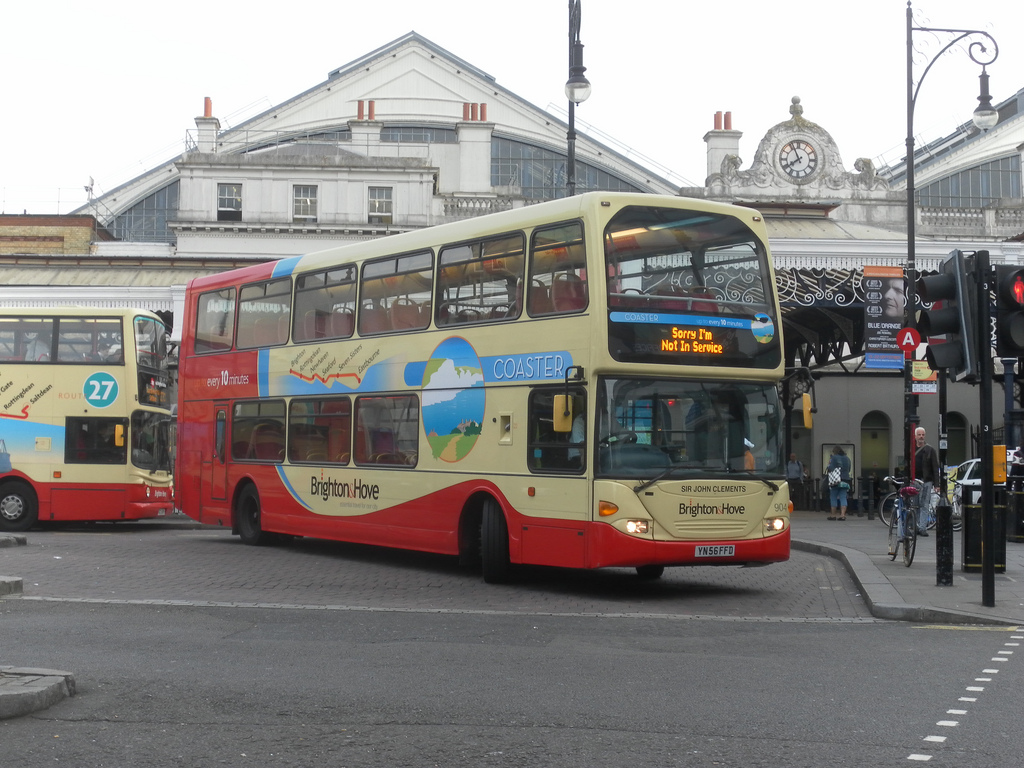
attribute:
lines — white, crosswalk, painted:
[918, 627, 1016, 742]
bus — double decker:
[215, 229, 743, 580]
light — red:
[928, 234, 1022, 358]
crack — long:
[155, 675, 631, 747]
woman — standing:
[812, 422, 940, 561]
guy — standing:
[870, 422, 968, 593]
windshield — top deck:
[613, 214, 817, 335]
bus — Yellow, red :
[131, 225, 849, 709]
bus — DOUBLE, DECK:
[172, 191, 816, 635]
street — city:
[82, 558, 759, 708]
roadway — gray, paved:
[107, 575, 214, 764]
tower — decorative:
[725, 55, 907, 529]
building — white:
[183, 48, 594, 191]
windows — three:
[211, 173, 415, 215]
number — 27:
[88, 359, 117, 412]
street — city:
[10, 505, 1015, 765]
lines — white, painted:
[924, 610, 1020, 738]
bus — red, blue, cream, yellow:
[151, 170, 821, 609]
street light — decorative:
[903, 21, 1014, 147]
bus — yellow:
[161, 158, 842, 643]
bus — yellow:
[147, 173, 861, 666]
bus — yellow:
[353, 247, 440, 341]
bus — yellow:
[102, 180, 900, 621]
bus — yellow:
[152, 184, 865, 591]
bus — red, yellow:
[139, 130, 814, 658]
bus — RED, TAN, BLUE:
[129, 178, 791, 576]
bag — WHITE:
[816, 463, 849, 492]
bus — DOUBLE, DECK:
[196, 197, 812, 565]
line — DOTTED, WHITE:
[907, 675, 970, 764]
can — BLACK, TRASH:
[958, 508, 987, 571]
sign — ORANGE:
[610, 325, 755, 360]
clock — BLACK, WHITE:
[794, 145, 812, 197]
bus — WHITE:
[174, 195, 790, 610]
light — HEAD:
[623, 506, 799, 552]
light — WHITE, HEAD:
[613, 510, 650, 539]